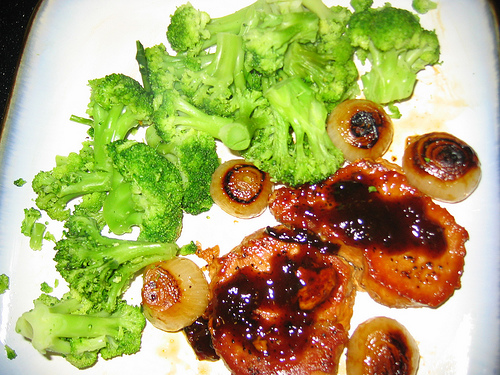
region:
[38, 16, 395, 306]
The broccoli is on the plate.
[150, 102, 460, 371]
The seafood is cooked.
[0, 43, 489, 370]
The seafood is next to the broccoli.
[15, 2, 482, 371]
The food is on the plate.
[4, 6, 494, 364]
The plate is white.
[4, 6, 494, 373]
The light is on the plate.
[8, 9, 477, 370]
the seafood has sauce on them.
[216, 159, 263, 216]
a brown spot.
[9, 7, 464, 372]
The food is ready.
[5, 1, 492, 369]
The broccoli is green.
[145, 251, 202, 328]
A fried water onion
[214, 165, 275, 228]
A fried water onion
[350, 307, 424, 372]
A fried water onion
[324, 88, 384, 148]
A fried water onion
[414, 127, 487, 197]
A fried water onion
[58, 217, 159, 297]
A Fresh green vegitable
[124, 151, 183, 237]
A Fresh green vegitable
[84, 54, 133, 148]
A Fresh green vegitable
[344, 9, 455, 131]
A Fresh green vegitable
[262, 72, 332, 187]
A Fresh green vegitable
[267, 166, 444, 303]
meat on the plate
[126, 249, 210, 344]
mushroom on the plate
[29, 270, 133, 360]
broccoli on the plate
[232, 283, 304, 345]
sauce on the meat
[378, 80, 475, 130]
sauce on the plate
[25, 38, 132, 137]
the plate is white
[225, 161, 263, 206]
ring on the onion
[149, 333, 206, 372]
sauce on hte plate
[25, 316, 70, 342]
bottom of the broccoli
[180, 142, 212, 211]
top of the broccoli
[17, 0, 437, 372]
light green broccoli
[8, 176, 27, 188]
crumb from the broccoli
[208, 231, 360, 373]
hunk of meat covered in sauce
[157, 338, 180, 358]
sauce smeared on the plate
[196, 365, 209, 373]
faint trace of sauce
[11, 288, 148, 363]
piece of broccoli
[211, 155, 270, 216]
black circle around the piece of food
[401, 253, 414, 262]
speck on the food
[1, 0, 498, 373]
food on a plate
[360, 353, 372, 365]
small light glare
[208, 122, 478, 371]
the food has a sauce on it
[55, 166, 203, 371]
the broccoli is green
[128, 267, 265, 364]
the onions are grilled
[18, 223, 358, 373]
the plate is white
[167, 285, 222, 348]
sauce is on the plate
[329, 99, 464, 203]
a blackened onion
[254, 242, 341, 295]
mushrooms are on the meat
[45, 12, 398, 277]
a large amount of broccoli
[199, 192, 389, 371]
two fillets on the plate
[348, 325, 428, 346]
carmelized onions